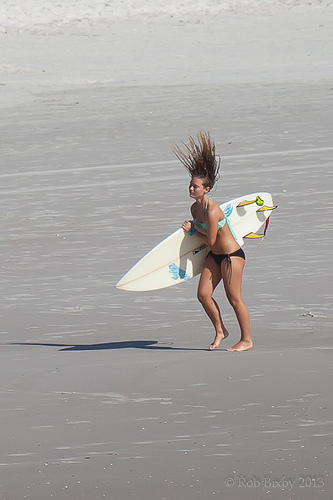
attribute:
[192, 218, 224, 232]
bikini top — green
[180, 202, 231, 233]
top — blue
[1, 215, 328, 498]
sand — wet 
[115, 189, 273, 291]
surfboard — WOMAN'S , PART 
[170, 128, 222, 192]
hair — brown 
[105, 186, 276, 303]
surfboard — big white 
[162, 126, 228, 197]
hair — brown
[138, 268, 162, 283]
surfboard — PART , WOMAN'S 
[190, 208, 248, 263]
black bikini — bottom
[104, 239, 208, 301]
surfboard — white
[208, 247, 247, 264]
black bottoms — black 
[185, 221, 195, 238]
wristband — blue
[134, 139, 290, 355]
woman — brown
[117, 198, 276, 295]
surfboard — white, blue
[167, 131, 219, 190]
hair — long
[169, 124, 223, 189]
hair — long, brown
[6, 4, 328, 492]
sand — wet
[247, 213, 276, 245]
strap — red  